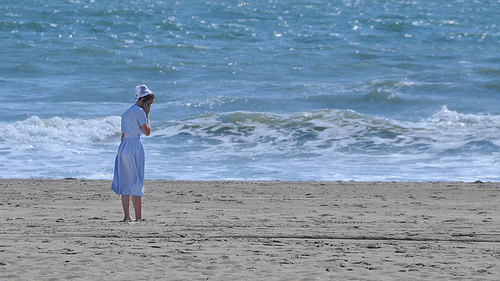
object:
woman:
[111, 84, 155, 222]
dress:
[110, 105, 148, 198]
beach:
[0, 177, 499, 280]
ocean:
[1, 0, 498, 182]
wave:
[0, 108, 499, 153]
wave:
[347, 75, 424, 104]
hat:
[135, 84, 152, 98]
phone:
[142, 100, 149, 107]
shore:
[0, 173, 499, 188]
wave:
[15, 20, 58, 35]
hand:
[143, 102, 151, 113]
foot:
[135, 218, 144, 221]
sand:
[0, 219, 321, 278]